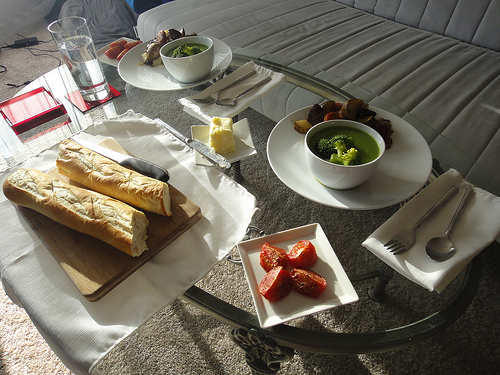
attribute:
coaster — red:
[60, 85, 128, 110]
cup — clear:
[58, 20, 138, 105]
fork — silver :
[383, 184, 457, 255]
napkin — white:
[361, 167, 498, 294]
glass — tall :
[55, 20, 94, 92]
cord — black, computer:
[5, 30, 42, 62]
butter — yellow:
[211, 116, 232, 153]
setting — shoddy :
[374, 214, 479, 272]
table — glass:
[9, 30, 488, 355]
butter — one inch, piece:
[210, 116, 235, 151]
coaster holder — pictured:
[0, 83, 60, 131]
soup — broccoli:
[306, 118, 384, 167]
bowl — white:
[144, 44, 218, 79]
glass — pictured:
[33, 9, 135, 121]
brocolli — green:
[317, 127, 374, 163]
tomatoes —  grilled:
[258, 241, 328, 302]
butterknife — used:
[152, 114, 234, 166]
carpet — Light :
[9, 61, 497, 373]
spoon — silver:
[420, 189, 480, 264]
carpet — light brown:
[148, 322, 180, 355]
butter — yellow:
[201, 104, 242, 166]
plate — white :
[268, 98, 434, 212]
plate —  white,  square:
[239, 222, 359, 328]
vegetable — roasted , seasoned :
[305, 104, 326, 125]